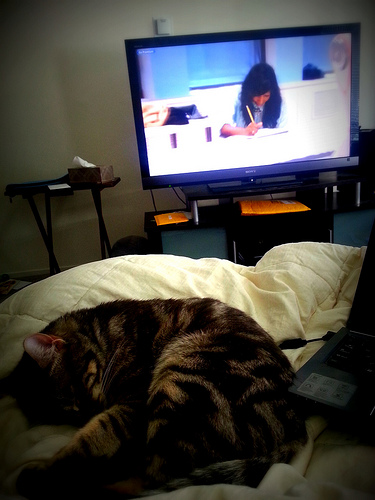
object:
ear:
[22, 329, 63, 364]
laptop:
[285, 225, 375, 420]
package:
[153, 209, 187, 226]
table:
[143, 206, 195, 258]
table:
[228, 196, 333, 265]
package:
[236, 197, 310, 218]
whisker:
[97, 352, 124, 395]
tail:
[72, 439, 295, 498]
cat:
[2, 295, 310, 500]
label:
[242, 167, 258, 175]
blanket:
[0, 236, 375, 500]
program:
[131, 31, 356, 177]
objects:
[5, 153, 118, 201]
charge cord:
[276, 327, 334, 352]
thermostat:
[153, 16, 168, 36]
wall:
[3, 4, 375, 282]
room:
[2, 1, 375, 500]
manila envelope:
[236, 193, 308, 214]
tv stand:
[220, 192, 339, 271]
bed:
[2, 241, 375, 500]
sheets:
[0, 238, 375, 500]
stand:
[148, 170, 340, 264]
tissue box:
[66, 154, 122, 190]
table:
[5, 162, 124, 275]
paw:
[53, 428, 101, 455]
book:
[283, 333, 374, 414]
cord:
[275, 330, 332, 351]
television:
[124, 18, 363, 190]